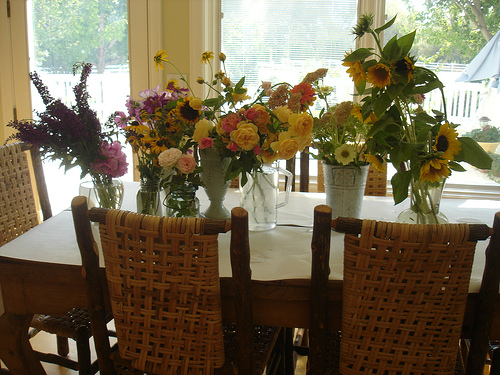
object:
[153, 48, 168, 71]
flowers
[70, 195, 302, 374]
chair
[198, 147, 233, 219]
vase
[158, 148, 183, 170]
flower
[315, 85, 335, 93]
flowers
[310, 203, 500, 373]
chair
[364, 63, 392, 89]
flower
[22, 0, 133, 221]
window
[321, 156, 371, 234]
vase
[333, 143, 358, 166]
flower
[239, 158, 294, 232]
flwer vase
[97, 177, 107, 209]
stems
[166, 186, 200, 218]
vase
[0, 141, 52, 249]
chair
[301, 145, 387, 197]
chair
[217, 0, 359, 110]
blind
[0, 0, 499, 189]
background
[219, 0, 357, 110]
outside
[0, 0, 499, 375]
room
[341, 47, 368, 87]
flowers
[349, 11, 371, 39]
flowers